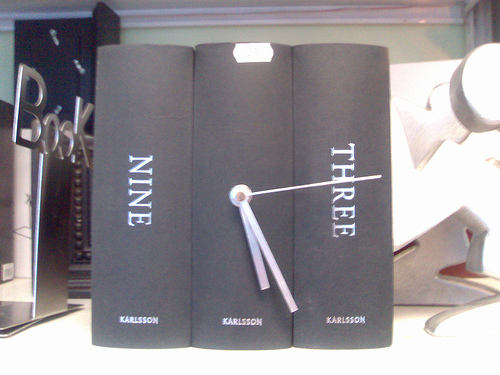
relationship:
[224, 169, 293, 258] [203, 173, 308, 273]
clack has hands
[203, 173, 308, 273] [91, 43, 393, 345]
hands of a black clock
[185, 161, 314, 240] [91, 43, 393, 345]
face of a black clock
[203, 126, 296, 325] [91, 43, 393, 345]
center of a black clock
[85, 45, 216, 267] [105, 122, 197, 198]
metal book has end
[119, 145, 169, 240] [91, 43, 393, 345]
nine on black clock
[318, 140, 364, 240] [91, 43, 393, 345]
three on black clock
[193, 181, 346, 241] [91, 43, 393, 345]
brand of black clock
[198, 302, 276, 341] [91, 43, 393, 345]
metal tag on black clock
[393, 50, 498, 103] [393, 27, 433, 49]
white trim on wall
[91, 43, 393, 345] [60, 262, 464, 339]
black clock on shelf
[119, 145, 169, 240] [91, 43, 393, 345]
silver writing on black clock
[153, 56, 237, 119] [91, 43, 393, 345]
dark spot next to black clock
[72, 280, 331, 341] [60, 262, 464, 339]
black beads on shelf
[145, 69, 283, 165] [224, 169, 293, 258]
black clock with silver hands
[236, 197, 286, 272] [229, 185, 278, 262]
second silver hand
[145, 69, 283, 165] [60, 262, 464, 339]
black clock on shelf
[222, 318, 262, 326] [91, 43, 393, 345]
metal tag on black clock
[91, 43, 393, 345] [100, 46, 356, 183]
black clock that looks like stack of books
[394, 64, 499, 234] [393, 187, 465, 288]
silver book stand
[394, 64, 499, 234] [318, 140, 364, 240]
silver inlaid word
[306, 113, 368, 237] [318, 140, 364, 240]
inlaid word three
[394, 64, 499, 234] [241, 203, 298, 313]
silver colored hand